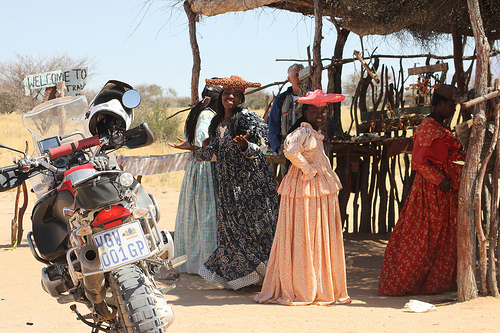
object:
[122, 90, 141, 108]
mirror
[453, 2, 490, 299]
post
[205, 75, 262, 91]
hat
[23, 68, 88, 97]
sign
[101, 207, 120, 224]
red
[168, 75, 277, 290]
woman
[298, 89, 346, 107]
hats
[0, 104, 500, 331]
road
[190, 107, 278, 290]
dress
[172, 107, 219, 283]
dress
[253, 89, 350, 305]
woman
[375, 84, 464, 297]
woman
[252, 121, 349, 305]
dress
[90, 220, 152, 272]
license plate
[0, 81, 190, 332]
motorcycle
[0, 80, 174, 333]
cycle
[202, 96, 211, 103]
ribbon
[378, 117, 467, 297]
red dress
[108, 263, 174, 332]
tire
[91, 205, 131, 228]
tailight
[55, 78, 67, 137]
post